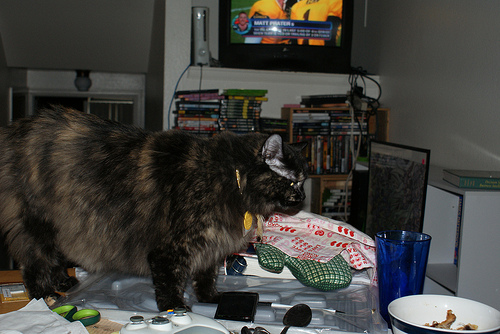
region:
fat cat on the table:
[18, 98, 323, 281]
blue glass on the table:
[373, 213, 435, 308]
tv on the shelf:
[213, 5, 351, 60]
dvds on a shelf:
[175, 81, 260, 137]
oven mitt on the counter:
[263, 238, 354, 284]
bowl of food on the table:
[391, 286, 499, 328]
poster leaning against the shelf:
[362, 135, 429, 232]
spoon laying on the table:
[276, 295, 317, 331]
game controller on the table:
[108, 306, 210, 331]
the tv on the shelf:
[216, 0, 355, 73]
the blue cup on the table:
[375, 228, 432, 328]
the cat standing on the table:
[0, 103, 306, 310]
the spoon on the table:
[278, 302, 311, 332]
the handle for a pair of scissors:
[50, 303, 100, 324]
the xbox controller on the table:
[120, 306, 230, 332]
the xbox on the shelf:
[193, 6, 209, 66]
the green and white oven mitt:
[255, 238, 352, 288]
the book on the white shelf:
[441, 167, 498, 189]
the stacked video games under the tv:
[171, 86, 368, 222]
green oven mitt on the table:
[253, 242, 359, 293]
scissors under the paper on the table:
[48, 287, 105, 331]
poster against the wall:
[347, 126, 467, 279]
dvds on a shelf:
[166, 78, 266, 130]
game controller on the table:
[116, 305, 226, 331]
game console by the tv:
[189, 4, 209, 69]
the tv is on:
[251, 1, 343, 48]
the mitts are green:
[267, 248, 347, 290]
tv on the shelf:
[226, 5, 371, 71]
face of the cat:
[232, 137, 299, 218]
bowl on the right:
[389, 291, 416, 329]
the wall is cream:
[400, 53, 485, 150]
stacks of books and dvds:
[175, 83, 272, 128]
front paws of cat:
[150, 260, 218, 306]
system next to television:
[187, 10, 220, 65]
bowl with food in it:
[385, 293, 497, 333]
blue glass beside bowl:
[376, 226, 498, 333]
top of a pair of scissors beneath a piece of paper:
[0, 297, 100, 331]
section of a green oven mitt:
[255, 243, 352, 290]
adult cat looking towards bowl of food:
[0, 105, 499, 332]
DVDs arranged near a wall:
[167, 72, 384, 222]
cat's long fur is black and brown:
[0, 103, 315, 313]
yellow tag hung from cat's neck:
[229, 165, 259, 237]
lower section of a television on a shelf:
[217, 1, 381, 94]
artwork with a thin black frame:
[365, 139, 430, 240]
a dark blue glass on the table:
[375, 227, 432, 319]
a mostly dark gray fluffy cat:
[1, 104, 309, 311]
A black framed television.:
[218, 1, 353, 68]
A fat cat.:
[2, 110, 314, 330]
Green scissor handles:
[50, 297, 105, 327]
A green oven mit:
[262, 242, 359, 289]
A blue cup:
[375, 228, 426, 315]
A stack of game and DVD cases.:
[178, 80, 267, 141]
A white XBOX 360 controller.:
[120, 303, 233, 332]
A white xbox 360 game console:
[190, 0, 212, 66]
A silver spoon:
[274, 296, 324, 332]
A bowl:
[380, 282, 497, 332]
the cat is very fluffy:
[0, 102, 310, 309]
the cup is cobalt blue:
[373, 230, 430, 325]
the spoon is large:
[278, 302, 311, 332]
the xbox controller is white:
[115, 305, 230, 332]